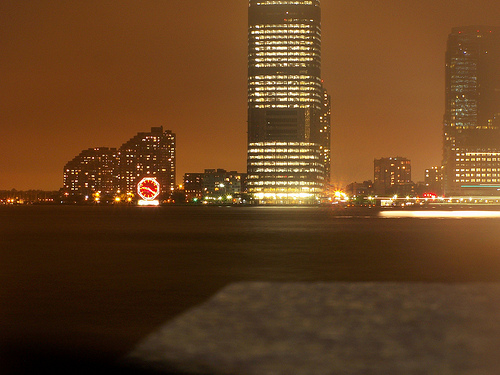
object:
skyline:
[1, 201, 500, 213]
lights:
[274, 43, 287, 52]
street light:
[134, 176, 160, 208]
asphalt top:
[121, 280, 498, 373]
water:
[23, 207, 495, 285]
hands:
[142, 186, 148, 190]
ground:
[380, 137, 423, 172]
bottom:
[242, 138, 327, 204]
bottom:
[441, 135, 498, 195]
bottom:
[62, 183, 137, 200]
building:
[182, 161, 241, 201]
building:
[371, 154, 412, 193]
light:
[460, 183, 498, 188]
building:
[450, 126, 498, 198]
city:
[2, 3, 498, 224]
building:
[63, 120, 175, 205]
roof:
[142, 125, 173, 136]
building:
[244, 2, 330, 207]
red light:
[490, 30, 492, 32]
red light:
[477, 30, 480, 33]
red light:
[458, 31, 461, 34]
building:
[440, 20, 498, 194]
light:
[329, 182, 351, 204]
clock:
[136, 177, 161, 206]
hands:
[148, 188, 157, 195]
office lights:
[252, 20, 302, 106]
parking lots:
[245, 104, 308, 142]